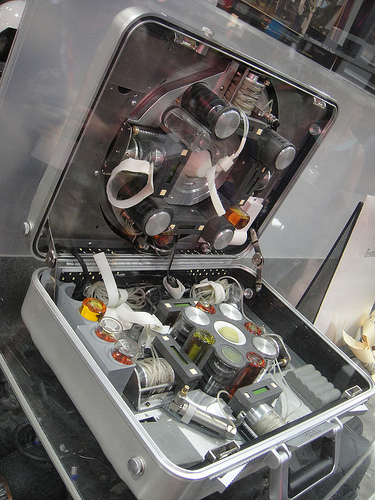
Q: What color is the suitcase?
A: Silver.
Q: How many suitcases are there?
A: 1.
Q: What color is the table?
A: Black.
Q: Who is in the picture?
A: No one.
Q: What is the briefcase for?
A: Scientific purposes.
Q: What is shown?
A: A briefcase.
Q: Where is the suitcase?
A: On a table.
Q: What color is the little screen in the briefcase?
A: Green.